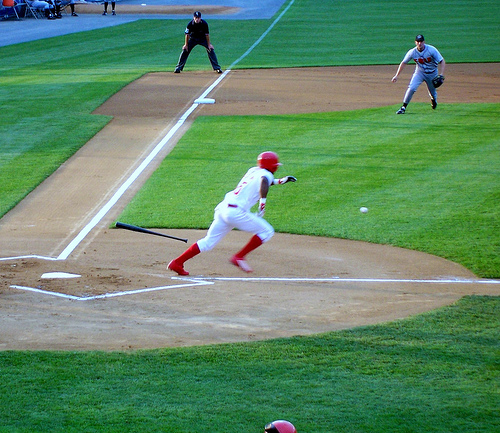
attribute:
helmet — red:
[256, 153, 281, 168]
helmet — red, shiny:
[246, 135, 293, 180]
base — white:
[42, 270, 79, 279]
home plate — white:
[41, 270, 81, 280]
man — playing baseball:
[156, 121, 328, 311]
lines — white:
[114, 67, 244, 216]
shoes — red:
[160, 258, 265, 279]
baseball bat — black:
[115, 219, 190, 249]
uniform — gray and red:
[392, 50, 459, 104]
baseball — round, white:
[360, 205, 370, 214]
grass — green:
[1, 294, 498, 431]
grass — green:
[110, 101, 498, 277]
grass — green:
[113, 1, 498, 72]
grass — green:
[1, 25, 116, 219]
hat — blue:
[414, 34, 426, 44]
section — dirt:
[2, 209, 484, 351]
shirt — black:
[174, 50, 212, 72]